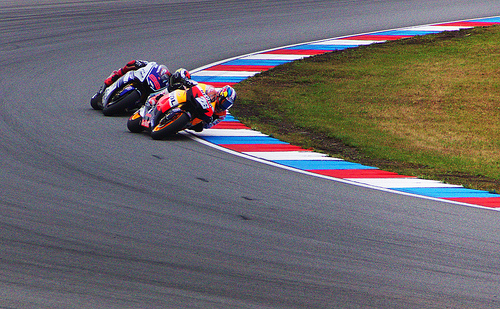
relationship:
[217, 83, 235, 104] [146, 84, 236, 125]
helmet of biker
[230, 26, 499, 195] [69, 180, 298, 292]
grass next to road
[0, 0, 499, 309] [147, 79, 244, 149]
road under biker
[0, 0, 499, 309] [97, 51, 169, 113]
road under biker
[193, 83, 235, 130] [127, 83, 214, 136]
biker turning bike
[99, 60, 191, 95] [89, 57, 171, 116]
biker turning bike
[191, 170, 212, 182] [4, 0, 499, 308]
mark on street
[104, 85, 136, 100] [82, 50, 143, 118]
front tire of bike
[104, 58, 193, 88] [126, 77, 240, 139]
person riding motorcycle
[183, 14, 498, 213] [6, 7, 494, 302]
colors in road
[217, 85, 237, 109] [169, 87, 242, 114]
helmet of person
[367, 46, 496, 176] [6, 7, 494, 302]
sand in road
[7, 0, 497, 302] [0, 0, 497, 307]
pavement on race track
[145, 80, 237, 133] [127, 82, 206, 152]
person on motorcycle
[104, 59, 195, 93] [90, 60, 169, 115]
person on motorcycle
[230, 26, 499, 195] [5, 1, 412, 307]
grass in center track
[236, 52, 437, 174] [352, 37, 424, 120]
tire tracks in grass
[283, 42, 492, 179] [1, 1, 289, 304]
grass next to race track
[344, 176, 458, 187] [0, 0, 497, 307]
white stripe next to race track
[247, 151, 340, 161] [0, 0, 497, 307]
white stripe next to race track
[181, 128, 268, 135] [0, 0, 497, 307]
white stripe next to race track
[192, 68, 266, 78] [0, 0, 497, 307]
white stripe next to race track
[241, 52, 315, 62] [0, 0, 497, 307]
white stripe next to race track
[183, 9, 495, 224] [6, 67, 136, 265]
stripe next to track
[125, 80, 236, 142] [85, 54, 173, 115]
motorcycle behind motorcycle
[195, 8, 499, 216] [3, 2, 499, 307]
white line along track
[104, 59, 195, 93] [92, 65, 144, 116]
person riding motorcycle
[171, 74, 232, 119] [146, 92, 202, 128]
person riding motorcycle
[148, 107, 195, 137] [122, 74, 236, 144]
tire of bike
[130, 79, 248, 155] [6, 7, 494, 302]
bike in road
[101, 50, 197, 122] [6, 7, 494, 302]
bike in road